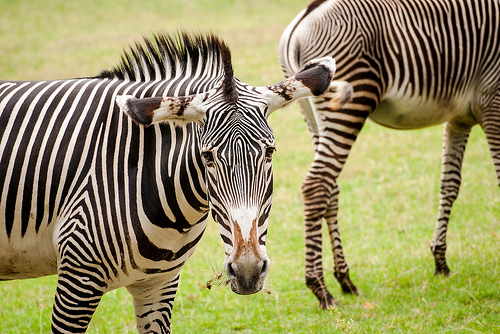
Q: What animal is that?
A: A zebra.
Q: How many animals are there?
A: Two.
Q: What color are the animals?
A: Black and white.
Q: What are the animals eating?
A: Grass.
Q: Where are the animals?
A: Grassland.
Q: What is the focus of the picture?
A: The Zebra.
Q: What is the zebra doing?
A: Eating.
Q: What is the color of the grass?
A: Green.